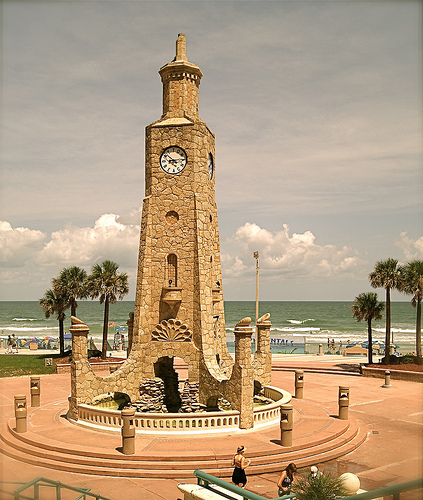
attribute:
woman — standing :
[276, 459, 297, 492]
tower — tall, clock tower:
[67, 32, 278, 431]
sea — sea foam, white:
[1, 300, 421, 339]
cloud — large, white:
[227, 217, 317, 275]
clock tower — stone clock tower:
[68, 32, 275, 433]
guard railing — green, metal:
[6, 475, 108, 498]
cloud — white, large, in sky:
[221, 215, 363, 280]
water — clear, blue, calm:
[227, 300, 417, 324]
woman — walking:
[231, 443, 250, 491]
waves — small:
[281, 295, 333, 343]